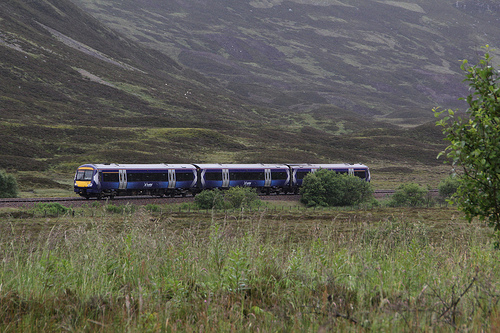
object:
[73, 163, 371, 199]
train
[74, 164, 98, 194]
front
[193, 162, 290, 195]
car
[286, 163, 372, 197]
car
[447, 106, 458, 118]
leaf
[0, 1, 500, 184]
hill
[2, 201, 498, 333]
grass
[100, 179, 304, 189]
stripe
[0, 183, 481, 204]
tracks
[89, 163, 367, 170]
roof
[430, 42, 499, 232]
tree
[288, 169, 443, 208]
shrub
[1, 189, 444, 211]
gravel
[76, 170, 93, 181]
window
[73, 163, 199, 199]
front car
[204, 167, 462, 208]
bush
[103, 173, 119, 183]
window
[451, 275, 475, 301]
branch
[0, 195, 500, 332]
ground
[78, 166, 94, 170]
stripe